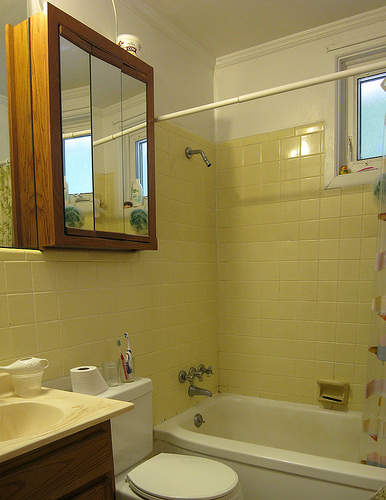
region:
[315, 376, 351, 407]
Soap dish with a black item inside it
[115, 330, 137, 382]
Clear glass holding two toothbrushes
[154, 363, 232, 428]
Moldy yellow bathroom tiles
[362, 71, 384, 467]
Clear shower curtain with patterns on it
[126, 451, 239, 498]
White toilet seat lid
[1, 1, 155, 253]
Brown wooden frame of medicine cabinet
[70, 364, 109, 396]
White roll of toilet paper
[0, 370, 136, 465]
Tan colored bathroom sink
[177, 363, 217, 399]
Faucet and taps of a bathtub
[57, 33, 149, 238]
Three mirrors on front of medicine cabinet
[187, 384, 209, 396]
silver faucet for bathtub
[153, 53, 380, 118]
white extendable shower curtain rod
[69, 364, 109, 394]
toilet paper roll on the back of the toilet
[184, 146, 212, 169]
small silver shower head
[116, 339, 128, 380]
white and orange toothbrush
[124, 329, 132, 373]
blue and white toothbrush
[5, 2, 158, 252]
wooden medicine cabinet with mirrors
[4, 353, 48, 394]
white container on the side of the sink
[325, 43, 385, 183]
partial window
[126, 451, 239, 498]
toilet lid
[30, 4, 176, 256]
a wooden medicine cabinet with mirror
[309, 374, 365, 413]
a soap holder on shower wall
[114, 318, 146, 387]
tooth brushes on back of toilet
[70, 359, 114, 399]
roll of toilet paper on back of toilet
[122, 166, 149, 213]
Bottle of soap reflected in mirror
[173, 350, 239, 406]
silver plumbing fixtures to tub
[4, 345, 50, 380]
white little teapot on counter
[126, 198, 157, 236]
Green shower poof reflected in mirror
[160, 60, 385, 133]
white pole to hold shower curtain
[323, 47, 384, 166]
a window with white trim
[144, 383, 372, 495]
this is abath tub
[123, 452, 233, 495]
this is a toilet bowl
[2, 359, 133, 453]
this is abathroom sink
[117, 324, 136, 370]
this is a toothbrush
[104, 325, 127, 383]
this is a toothbrush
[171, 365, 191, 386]
this is a tap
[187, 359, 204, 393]
this is a tap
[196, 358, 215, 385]
this is a tap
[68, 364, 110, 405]
this is a roll of tissue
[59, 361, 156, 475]
this is a toilet cistern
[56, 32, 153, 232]
3-panel mirror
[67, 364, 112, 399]
Roll of toilet paper on top of the toilet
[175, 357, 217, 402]
Silver faucet and dials to the bath tub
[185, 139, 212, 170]
Silver showerhead on yellow wall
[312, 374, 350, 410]
Soap holder on the side of the tub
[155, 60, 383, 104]
White shower curtain rod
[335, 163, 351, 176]
Yellow rubber ducky sitting on a window sill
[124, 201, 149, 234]
Blue loofa showing in the mirror's reflection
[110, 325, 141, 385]
Two toothbrushes sitting in a cup on the toilet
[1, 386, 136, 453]
Ivoery and beige marble sink and countertop